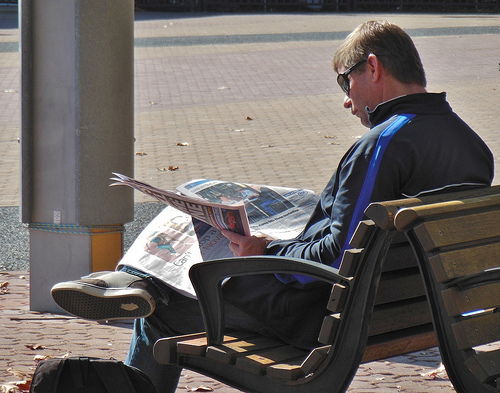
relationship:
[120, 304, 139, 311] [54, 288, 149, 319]
chewing gum on sole of shoe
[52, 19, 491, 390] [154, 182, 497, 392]
man sitting on bench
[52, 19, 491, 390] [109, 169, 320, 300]
man reading a newspaper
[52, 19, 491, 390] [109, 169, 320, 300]
man holding newspaper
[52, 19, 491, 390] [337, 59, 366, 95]
man wearing sunglasses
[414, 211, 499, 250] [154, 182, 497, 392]
slat on bench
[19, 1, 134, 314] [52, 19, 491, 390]
pillar in front of man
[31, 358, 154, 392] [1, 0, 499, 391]
bag on ground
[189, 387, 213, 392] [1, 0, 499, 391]
leaf on ground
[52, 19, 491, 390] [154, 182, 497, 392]
man sitting on a bench